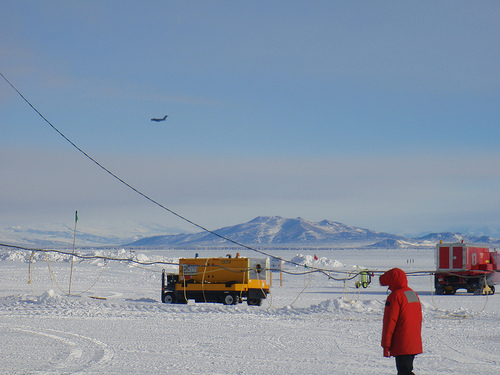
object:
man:
[379, 267, 425, 375]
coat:
[379, 267, 423, 356]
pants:
[395, 355, 416, 375]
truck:
[161, 253, 270, 307]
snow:
[2, 244, 499, 372]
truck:
[435, 240, 500, 295]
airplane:
[151, 115, 168, 123]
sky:
[0, 1, 498, 233]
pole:
[68, 211, 79, 296]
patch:
[404, 291, 419, 303]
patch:
[385, 302, 390, 306]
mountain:
[0, 215, 500, 248]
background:
[2, 174, 499, 266]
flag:
[314, 254, 318, 260]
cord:
[0, 72, 437, 277]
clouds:
[0, 57, 497, 209]